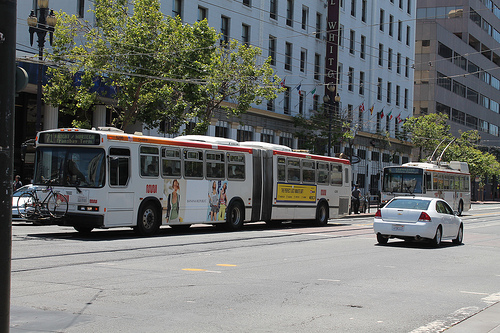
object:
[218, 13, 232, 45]
glass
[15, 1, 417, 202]
building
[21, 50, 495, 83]
wire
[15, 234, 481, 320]
street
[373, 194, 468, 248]
car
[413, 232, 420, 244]
exhaust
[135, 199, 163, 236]
wheel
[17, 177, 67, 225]
bike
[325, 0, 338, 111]
sign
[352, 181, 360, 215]
person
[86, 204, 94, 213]
light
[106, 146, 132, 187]
window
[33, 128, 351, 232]
bus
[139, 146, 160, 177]
window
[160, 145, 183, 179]
window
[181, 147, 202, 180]
window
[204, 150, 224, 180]
window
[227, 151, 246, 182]
window